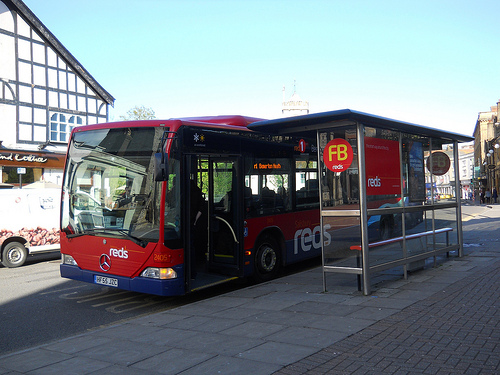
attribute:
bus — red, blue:
[51, 111, 332, 308]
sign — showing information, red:
[320, 135, 354, 179]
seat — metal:
[344, 221, 456, 291]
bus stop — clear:
[237, 103, 481, 300]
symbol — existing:
[95, 251, 115, 275]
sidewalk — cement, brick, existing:
[0, 203, 499, 375]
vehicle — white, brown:
[0, 182, 67, 270]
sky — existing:
[23, 1, 500, 136]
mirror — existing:
[151, 127, 179, 185]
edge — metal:
[354, 123, 370, 294]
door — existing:
[205, 153, 240, 277]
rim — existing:
[6, 244, 26, 266]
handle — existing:
[212, 213, 241, 245]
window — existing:
[242, 155, 294, 221]